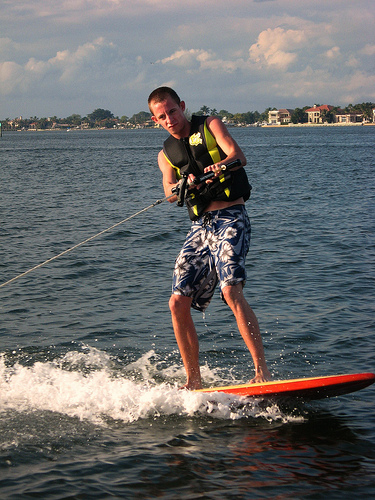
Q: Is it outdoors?
A: Yes, it is outdoors.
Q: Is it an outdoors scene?
A: Yes, it is outdoors.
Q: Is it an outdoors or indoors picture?
A: It is outdoors.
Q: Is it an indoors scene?
A: No, it is outdoors.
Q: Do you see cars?
A: No, there are no cars.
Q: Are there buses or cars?
A: No, there are no cars or buses.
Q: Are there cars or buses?
A: No, there are no cars or buses.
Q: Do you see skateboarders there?
A: No, there are no skateboarders.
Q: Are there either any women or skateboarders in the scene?
A: No, there are no skateboarders or women.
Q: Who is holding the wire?
A: The boy is holding the wire.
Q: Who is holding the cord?
A: The boy is holding the wire.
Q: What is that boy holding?
A: The boy is holding the wire.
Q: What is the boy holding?
A: The boy is holding the wire.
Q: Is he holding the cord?
A: Yes, the boy is holding the cord.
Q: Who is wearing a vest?
A: The boy is wearing a vest.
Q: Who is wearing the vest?
A: The boy is wearing a vest.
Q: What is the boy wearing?
A: The boy is wearing a vest.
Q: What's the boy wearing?
A: The boy is wearing a vest.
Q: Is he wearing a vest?
A: Yes, the boy is wearing a vest.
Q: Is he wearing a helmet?
A: No, the boy is wearing a vest.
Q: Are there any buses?
A: No, there are no buses.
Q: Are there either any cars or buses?
A: No, there are no buses or cars.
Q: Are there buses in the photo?
A: No, there are no buses.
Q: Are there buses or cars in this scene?
A: No, there are no buses or cars.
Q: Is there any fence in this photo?
A: No, there are no fences.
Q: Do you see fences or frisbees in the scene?
A: No, there are no fences or frisbees.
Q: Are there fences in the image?
A: No, there are no fences.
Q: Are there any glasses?
A: No, there are no glasses.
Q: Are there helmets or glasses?
A: No, there are no glasses or helmets.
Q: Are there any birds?
A: No, there are no birds.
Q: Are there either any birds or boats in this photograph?
A: No, there are no birds or boats.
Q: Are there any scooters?
A: No, there are no scooters.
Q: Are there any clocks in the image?
A: No, there are no clocks.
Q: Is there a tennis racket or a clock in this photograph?
A: No, there are no clocks or rackets.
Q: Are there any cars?
A: No, there are no cars.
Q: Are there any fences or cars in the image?
A: No, there are no cars or fences.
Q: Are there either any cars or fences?
A: No, there are no cars or fences.